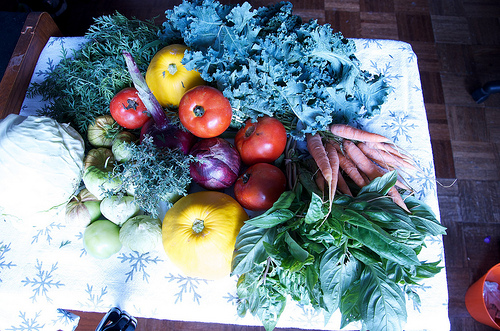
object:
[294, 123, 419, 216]
carrots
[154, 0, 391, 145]
kale